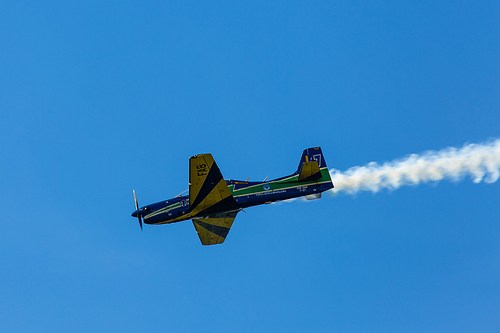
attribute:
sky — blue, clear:
[0, 1, 499, 332]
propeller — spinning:
[130, 189, 145, 234]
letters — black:
[197, 161, 208, 178]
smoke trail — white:
[268, 136, 499, 204]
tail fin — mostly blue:
[296, 146, 327, 173]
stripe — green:
[142, 167, 331, 217]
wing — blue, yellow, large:
[187, 152, 236, 210]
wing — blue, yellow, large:
[192, 209, 239, 245]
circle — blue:
[262, 183, 270, 192]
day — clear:
[1, 0, 500, 332]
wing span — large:
[189, 153, 238, 245]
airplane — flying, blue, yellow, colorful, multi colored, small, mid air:
[131, 142, 336, 246]